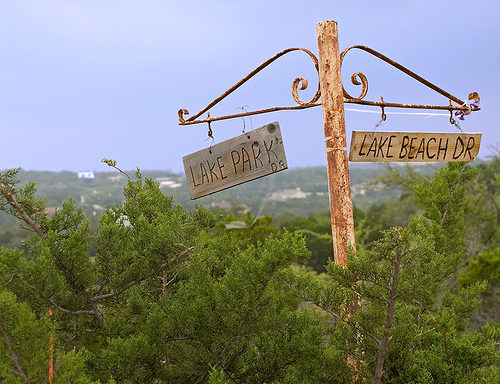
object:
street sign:
[180, 120, 288, 200]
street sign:
[349, 129, 484, 163]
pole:
[314, 20, 359, 268]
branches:
[0, 174, 108, 329]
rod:
[177, 48, 322, 125]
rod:
[340, 44, 483, 112]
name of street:
[190, 139, 286, 187]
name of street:
[357, 134, 476, 160]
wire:
[236, 104, 254, 138]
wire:
[448, 99, 466, 139]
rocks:
[293, 193, 308, 198]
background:
[0, 0, 499, 383]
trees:
[0, 165, 196, 383]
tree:
[273, 226, 457, 383]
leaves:
[123, 181, 158, 255]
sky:
[0, 0, 499, 170]